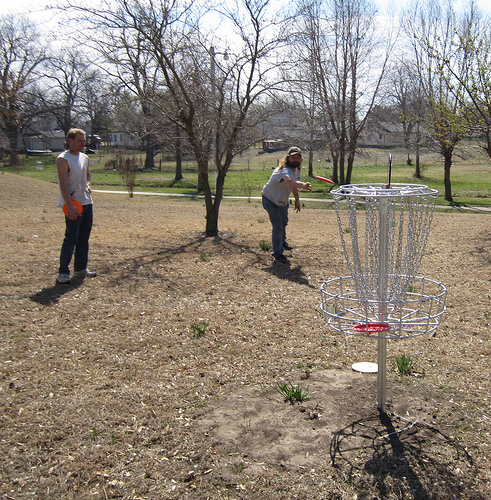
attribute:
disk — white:
[348, 359, 380, 375]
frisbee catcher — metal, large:
[313, 134, 455, 437]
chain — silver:
[376, 197, 405, 267]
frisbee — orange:
[61, 198, 84, 215]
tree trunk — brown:
[439, 155, 459, 201]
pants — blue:
[56, 202, 98, 273]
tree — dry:
[416, 85, 487, 197]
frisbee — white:
[354, 318, 396, 336]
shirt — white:
[56, 149, 93, 206]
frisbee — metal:
[310, 152, 332, 199]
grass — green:
[273, 375, 310, 405]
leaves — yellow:
[409, 33, 489, 141]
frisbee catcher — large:
[315, 156, 468, 433]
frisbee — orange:
[350, 310, 394, 337]